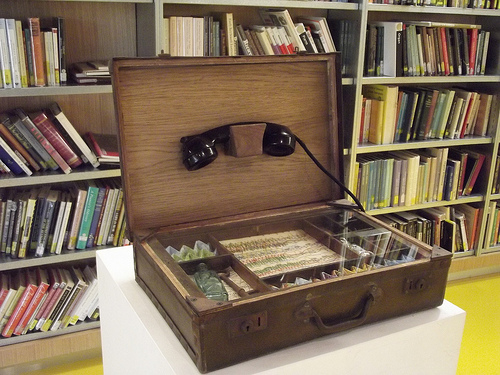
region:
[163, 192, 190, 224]
part of a board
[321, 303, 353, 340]
part of a handle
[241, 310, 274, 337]
part of a lock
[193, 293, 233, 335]
edge of a case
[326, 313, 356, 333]
part of a handle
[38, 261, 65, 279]
edge of a shelf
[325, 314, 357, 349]
part of a handle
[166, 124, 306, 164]
black plastic telephone receiver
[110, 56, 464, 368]
antique wood lined suitcase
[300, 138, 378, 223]
black telephone plastic coated wire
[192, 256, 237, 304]
clear antique glass bottle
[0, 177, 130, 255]
shelf of library books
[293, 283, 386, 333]
brown metal suitcase handle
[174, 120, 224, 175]
black telephone hearing piece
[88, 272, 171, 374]
white plastic display stand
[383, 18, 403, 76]
white book with black title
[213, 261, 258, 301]
antique large metal key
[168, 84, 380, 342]
this is a locker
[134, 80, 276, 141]
the locker is brown in color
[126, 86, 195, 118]
the locker is wooden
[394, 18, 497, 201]
this is a book shelve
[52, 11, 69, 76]
this is a book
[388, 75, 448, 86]
thew shelve is wooden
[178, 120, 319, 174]
this is a telephone line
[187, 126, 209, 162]
the telephone is black in color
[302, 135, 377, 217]
this is the cable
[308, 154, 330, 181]
the cable is black in color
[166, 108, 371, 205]
a corded telephone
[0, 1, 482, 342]
there are shelves of library books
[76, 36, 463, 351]
an old wooden briefcase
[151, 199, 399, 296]
there is glass over the compartment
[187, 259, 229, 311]
a glass bottle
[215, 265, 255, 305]
an old key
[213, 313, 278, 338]
the lock has been rusted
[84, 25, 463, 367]
the briefcase is on display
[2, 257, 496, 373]
the floor is yellow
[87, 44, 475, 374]
the briefcase is brown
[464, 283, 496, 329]
yellow color on floor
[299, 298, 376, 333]
handle on brown box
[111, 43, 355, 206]
lid on brown box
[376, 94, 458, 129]
books on book shelf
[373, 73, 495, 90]
divider in the book shelf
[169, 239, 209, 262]
white fabric in the brown box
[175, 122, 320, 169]
old fashioned black telephone receiver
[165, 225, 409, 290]
compartments in the box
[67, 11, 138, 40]
light brown wood on the wall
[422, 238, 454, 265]
brass holder on side of box